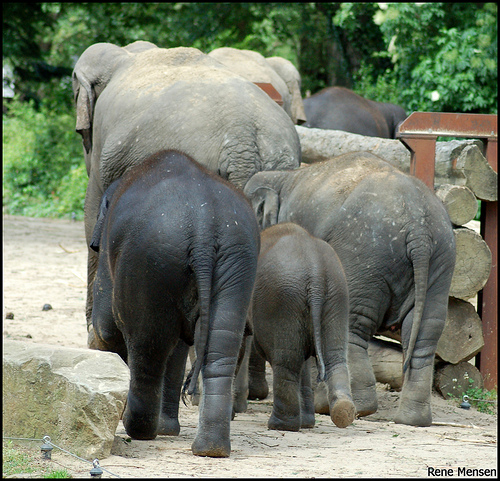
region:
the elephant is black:
[113, 156, 257, 456]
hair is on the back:
[131, 151, 231, 186]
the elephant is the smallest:
[271, 208, 356, 437]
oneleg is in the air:
[318, 355, 368, 425]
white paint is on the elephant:
[345, 191, 400, 247]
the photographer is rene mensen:
[422, 457, 499, 480]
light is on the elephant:
[148, 50, 239, 110]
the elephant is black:
[321, 91, 400, 135]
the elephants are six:
[82, 42, 412, 455]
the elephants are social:
[71, 24, 448, 437]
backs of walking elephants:
[74, 41, 450, 450]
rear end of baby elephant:
[253, 226, 358, 431]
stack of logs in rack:
[297, 124, 498, 386]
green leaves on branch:
[376, 5, 498, 86]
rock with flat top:
[4, 337, 135, 464]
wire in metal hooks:
[40, 434, 103, 474]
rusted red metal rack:
[398, 109, 496, 386]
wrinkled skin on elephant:
[97, 138, 138, 178]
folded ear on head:
[73, 63, 101, 137]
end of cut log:
[443, 232, 490, 294]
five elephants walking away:
[62, 28, 479, 440]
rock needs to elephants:
[12, 332, 126, 479]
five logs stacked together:
[249, 101, 499, 389]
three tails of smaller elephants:
[177, 267, 437, 416]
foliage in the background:
[5, 6, 476, 199]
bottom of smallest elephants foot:
[329, 395, 354, 422]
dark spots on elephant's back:
[117, 152, 258, 208]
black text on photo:
[423, 463, 495, 480]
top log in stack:
[287, 125, 494, 196]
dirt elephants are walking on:
[20, 216, 482, 471]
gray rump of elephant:
[273, 256, 310, 346]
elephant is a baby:
[296, 236, 308, 267]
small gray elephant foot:
[326, 393, 355, 438]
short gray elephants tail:
[307, 282, 337, 372]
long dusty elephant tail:
[406, 238, 435, 363]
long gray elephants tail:
[196, 244, 208, 421]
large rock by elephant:
[38, 370, 62, 400]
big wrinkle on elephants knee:
[201, 343, 228, 385]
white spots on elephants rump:
[347, 223, 433, 278]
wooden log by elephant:
[467, 228, 489, 279]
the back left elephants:
[83, 138, 273, 460]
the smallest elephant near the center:
[232, 216, 374, 445]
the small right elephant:
[232, 158, 458, 443]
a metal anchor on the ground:
[32, 428, 58, 466]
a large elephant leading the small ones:
[49, 20, 334, 392]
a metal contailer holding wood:
[386, 103, 498, 410]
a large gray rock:
[0, 331, 133, 459]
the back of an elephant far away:
[294, 88, 422, 138]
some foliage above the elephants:
[392, 23, 490, 116]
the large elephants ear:
[64, 60, 106, 153]